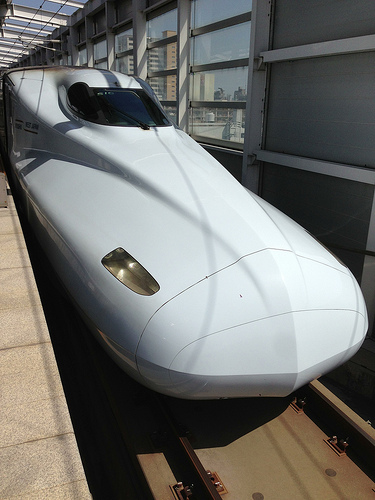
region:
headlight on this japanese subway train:
[100, 247, 160, 297]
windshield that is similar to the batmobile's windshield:
[65, 81, 170, 127]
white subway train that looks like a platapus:
[2, 65, 368, 400]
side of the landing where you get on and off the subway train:
[0, 179, 93, 498]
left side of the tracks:
[147, 392, 221, 499]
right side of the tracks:
[310, 378, 373, 444]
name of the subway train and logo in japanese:
[12, 118, 40, 135]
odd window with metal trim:
[186, 0, 252, 146]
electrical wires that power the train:
[0, 0, 68, 65]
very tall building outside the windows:
[163, 29, 180, 111]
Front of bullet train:
[9, 61, 347, 392]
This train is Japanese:
[13, 74, 63, 165]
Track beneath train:
[168, 428, 220, 498]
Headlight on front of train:
[95, 240, 165, 310]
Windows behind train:
[43, 36, 253, 137]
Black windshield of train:
[69, 83, 165, 131]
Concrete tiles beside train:
[2, 196, 86, 497]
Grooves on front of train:
[141, 266, 359, 337]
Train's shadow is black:
[83, 372, 274, 440]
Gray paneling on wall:
[268, 68, 368, 165]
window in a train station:
[183, 1, 259, 154]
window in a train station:
[140, 0, 181, 128]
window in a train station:
[108, 6, 139, 73]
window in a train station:
[74, 31, 91, 67]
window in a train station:
[64, 47, 76, 66]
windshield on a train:
[58, 81, 167, 130]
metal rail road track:
[152, 390, 219, 499]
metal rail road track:
[292, 374, 373, 470]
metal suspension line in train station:
[0, 1, 50, 66]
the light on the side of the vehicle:
[92, 234, 163, 302]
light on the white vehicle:
[93, 244, 167, 307]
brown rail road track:
[86, 340, 259, 497]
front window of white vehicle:
[66, 68, 176, 129]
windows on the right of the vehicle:
[36, 11, 263, 132]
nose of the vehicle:
[125, 245, 358, 398]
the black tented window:
[63, 75, 178, 139]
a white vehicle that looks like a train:
[15, 60, 355, 396]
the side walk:
[1, 317, 96, 487]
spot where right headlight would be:
[286, 206, 350, 277]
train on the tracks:
[8, 51, 374, 497]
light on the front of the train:
[100, 246, 164, 303]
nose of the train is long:
[40, 148, 372, 421]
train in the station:
[6, 2, 373, 488]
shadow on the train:
[11, 105, 105, 183]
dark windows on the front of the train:
[54, 75, 182, 138]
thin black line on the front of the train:
[163, 302, 369, 382]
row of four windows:
[190, 2, 255, 143]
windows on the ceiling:
[0, 0, 75, 66]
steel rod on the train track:
[156, 408, 221, 494]